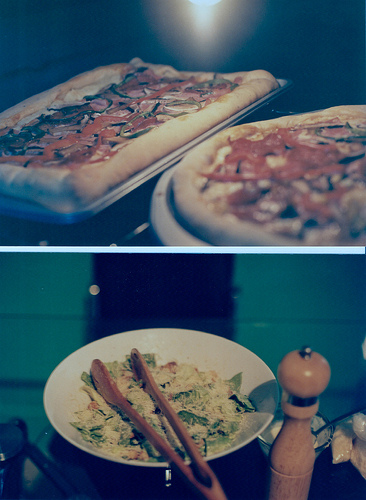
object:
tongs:
[89, 348, 226, 499]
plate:
[43, 328, 280, 469]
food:
[170, 104, 365, 246]